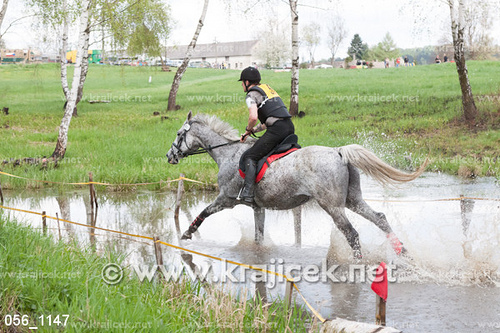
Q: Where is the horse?
A: Pond.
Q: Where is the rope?
A: Around pond.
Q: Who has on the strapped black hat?
A: A lady.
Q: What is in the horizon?
A: Buildings.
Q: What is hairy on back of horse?
A: Tail.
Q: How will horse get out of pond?
A: Jump.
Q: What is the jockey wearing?
A: A helmet and riding gear.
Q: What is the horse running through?
A: Water.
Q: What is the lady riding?
A: A horse.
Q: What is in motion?
A: The horse.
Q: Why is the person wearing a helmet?
A: For protection.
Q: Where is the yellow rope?
A: Around the water.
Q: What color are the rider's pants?
A: Black.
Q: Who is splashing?
A: The horse.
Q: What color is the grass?
A: Green.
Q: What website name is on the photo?
A: www.krajicek.net.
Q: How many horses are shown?
A: One.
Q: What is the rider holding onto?
A: The reins.